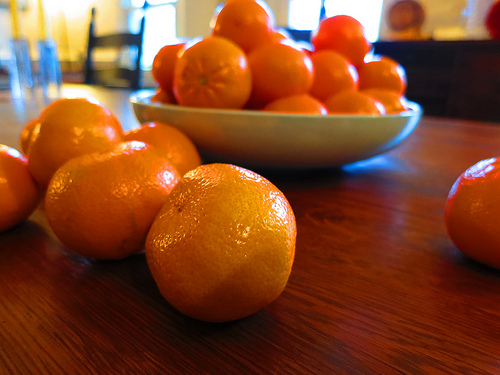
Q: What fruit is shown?
A: Oranges.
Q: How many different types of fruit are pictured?
A: One.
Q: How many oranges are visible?
A: Eighteen.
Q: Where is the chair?
A: In the background near the wall.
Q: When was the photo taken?
A: During the day.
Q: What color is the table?
A: Brown.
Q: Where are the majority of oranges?
A: In a bowl on the table.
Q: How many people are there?
A: None.